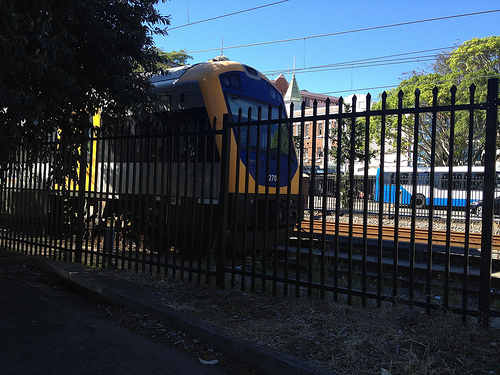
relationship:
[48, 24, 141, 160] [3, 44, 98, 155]
tree has leaves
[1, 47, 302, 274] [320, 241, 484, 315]
train has tracks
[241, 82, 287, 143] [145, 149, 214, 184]
blue and white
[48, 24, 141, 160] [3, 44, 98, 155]
tree in corner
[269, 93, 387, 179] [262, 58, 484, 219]
buildings in background